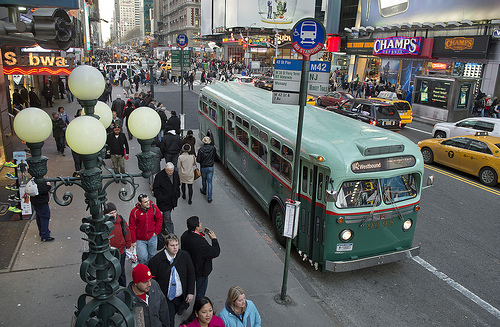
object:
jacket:
[144, 247, 196, 299]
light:
[403, 220, 411, 229]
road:
[462, 69, 496, 324]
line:
[410, 250, 500, 317]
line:
[426, 164, 500, 196]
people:
[218, 286, 261, 327]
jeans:
[200, 164, 214, 200]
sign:
[289, 17, 327, 58]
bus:
[196, 80, 433, 272]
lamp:
[13, 65, 161, 326]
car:
[431, 116, 499, 139]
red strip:
[196, 109, 421, 215]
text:
[367, 220, 396, 229]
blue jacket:
[216, 299, 261, 326]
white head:
[164, 161, 174, 171]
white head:
[202, 137, 211, 145]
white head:
[115, 94, 121, 98]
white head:
[486, 93, 491, 98]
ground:
[361, 268, 413, 302]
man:
[116, 263, 169, 325]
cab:
[416, 131, 499, 185]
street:
[421, 161, 438, 216]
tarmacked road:
[326, 304, 439, 325]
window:
[334, 179, 382, 209]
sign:
[373, 36, 424, 57]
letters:
[373, 38, 416, 52]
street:
[234, 51, 342, 258]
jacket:
[128, 201, 163, 242]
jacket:
[100, 210, 133, 255]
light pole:
[25, 98, 159, 327]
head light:
[338, 230, 354, 240]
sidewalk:
[21, 248, 66, 313]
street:
[306, 269, 419, 284]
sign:
[352, 157, 416, 173]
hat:
[131, 263, 156, 284]